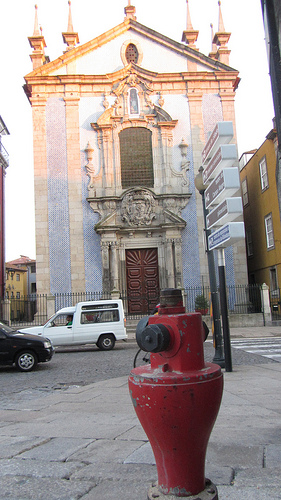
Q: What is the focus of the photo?
A: Hydrant.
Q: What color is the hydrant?
A: Red.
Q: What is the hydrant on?
A: Sidewalk.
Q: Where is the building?
A: Background.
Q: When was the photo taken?
A: Daytime.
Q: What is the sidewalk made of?
A: Stone.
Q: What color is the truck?
A: White.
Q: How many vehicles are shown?
A: Two.